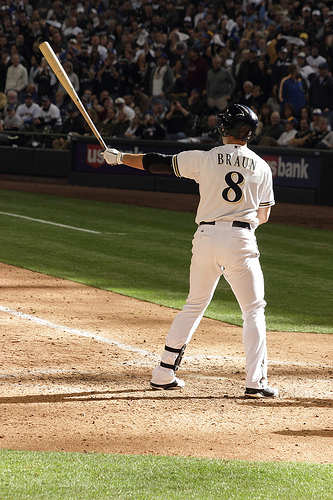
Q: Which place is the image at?
A: It is at the field.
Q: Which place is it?
A: It is a field.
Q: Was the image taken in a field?
A: Yes, it was taken in a field.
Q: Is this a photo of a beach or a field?
A: It is showing a field.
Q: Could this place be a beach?
A: No, it is a field.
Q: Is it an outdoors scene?
A: Yes, it is outdoors.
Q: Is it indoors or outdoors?
A: It is outdoors.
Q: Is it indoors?
A: No, it is outdoors.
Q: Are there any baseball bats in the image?
A: Yes, there is a baseball bat.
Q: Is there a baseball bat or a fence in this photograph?
A: Yes, there is a baseball bat.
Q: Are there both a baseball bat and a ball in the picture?
A: No, there is a baseball bat but no balls.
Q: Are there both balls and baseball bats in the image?
A: No, there is a baseball bat but no balls.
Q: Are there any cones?
A: No, there are no cones.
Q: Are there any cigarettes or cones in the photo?
A: No, there are no cones or cigarettes.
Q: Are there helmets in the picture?
A: Yes, there is a helmet.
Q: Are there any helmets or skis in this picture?
A: Yes, there is a helmet.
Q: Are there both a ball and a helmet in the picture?
A: No, there is a helmet but no balls.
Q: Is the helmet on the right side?
A: Yes, the helmet is on the right of the image.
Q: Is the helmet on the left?
A: No, the helmet is on the right of the image.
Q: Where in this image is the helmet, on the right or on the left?
A: The helmet is on the right of the image.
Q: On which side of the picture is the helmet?
A: The helmet is on the right of the image.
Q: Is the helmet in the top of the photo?
A: Yes, the helmet is in the top of the image.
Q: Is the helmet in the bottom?
A: No, the helmet is in the top of the image.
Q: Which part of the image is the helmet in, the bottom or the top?
A: The helmet is in the top of the image.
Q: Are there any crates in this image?
A: No, there are no crates.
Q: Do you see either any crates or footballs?
A: No, there are no crates or footballs.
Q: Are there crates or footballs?
A: No, there are no crates or footballs.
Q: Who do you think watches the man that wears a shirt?
A: The crowd watches the man.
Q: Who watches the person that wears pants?
A: The crowd watches the man.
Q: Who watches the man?
A: The crowd watches the man.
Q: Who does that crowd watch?
A: The crowd watches the man.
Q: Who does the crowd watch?
A: The crowd watches the man.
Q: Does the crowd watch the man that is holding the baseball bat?
A: Yes, the crowd watches the man.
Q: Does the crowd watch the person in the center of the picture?
A: Yes, the crowd watches the man.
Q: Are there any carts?
A: No, there are no carts.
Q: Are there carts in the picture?
A: No, there are no carts.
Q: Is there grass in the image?
A: Yes, there is grass.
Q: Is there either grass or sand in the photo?
A: Yes, there is grass.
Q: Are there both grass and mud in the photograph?
A: No, there is grass but no mud.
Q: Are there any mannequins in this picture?
A: No, there are no mannequins.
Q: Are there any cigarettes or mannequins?
A: No, there are no mannequins or cigarettes.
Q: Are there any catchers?
A: No, there are no catchers.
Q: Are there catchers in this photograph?
A: No, there are no catchers.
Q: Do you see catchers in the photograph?
A: No, there are no catchers.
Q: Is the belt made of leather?
A: Yes, the belt is made of leather.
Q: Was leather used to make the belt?
A: Yes, the belt is made of leather.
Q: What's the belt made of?
A: The belt is made of leather.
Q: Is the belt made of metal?
A: No, the belt is made of leather.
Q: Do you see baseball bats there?
A: Yes, there is a baseball bat.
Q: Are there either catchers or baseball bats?
A: Yes, there is a baseball bat.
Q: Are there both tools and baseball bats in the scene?
A: No, there is a baseball bat but no tools.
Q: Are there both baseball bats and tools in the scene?
A: No, there is a baseball bat but no tools.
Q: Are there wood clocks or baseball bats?
A: Yes, there is a wood baseball bat.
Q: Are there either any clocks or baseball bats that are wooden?
A: Yes, the baseball bat is wooden.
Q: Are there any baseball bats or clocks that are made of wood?
A: Yes, the baseball bat is made of wood.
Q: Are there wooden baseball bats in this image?
A: Yes, there is a wood baseball bat.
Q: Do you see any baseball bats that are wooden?
A: Yes, there is a baseball bat that is wooden.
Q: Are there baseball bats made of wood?
A: Yes, there is a baseball bat that is made of wood.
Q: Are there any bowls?
A: No, there are no bowls.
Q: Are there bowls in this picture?
A: No, there are no bowls.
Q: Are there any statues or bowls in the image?
A: No, there are no bowls or statues.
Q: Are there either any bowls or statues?
A: No, there are no bowls or statues.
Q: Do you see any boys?
A: No, there are no boys.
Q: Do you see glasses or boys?
A: No, there are no boys or glasses.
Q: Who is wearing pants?
A: The man is wearing pants.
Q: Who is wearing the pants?
A: The man is wearing pants.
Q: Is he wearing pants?
A: Yes, the man is wearing pants.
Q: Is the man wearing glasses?
A: No, the man is wearing pants.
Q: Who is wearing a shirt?
A: The man is wearing a shirt.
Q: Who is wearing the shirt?
A: The man is wearing a shirt.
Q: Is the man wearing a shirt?
A: Yes, the man is wearing a shirt.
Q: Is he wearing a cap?
A: No, the man is wearing a shirt.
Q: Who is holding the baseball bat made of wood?
A: The man is holding the baseball bat.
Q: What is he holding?
A: The man is holding the baseball bat.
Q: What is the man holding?
A: The man is holding the baseball bat.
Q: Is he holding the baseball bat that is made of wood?
A: Yes, the man is holding the baseball bat.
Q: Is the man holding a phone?
A: No, the man is holding the baseball bat.